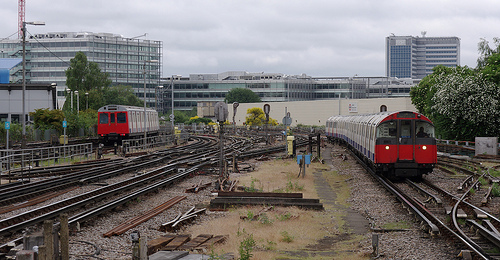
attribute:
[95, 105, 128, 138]
front — red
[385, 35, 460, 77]
building — large, distant, tall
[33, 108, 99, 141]
shrubs — green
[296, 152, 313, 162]
sign — blue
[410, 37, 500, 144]
trees — green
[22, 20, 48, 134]
light pole — tall, silver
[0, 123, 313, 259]
tracks — metal, many, rusty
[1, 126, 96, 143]
fence — metal, small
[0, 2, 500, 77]
sky — cloudy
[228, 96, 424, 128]
wall — white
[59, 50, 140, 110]
trees — green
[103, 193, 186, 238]
slat — wooden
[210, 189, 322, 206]
slats — steel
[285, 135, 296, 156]
pole — yellow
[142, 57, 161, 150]
light pole — tall